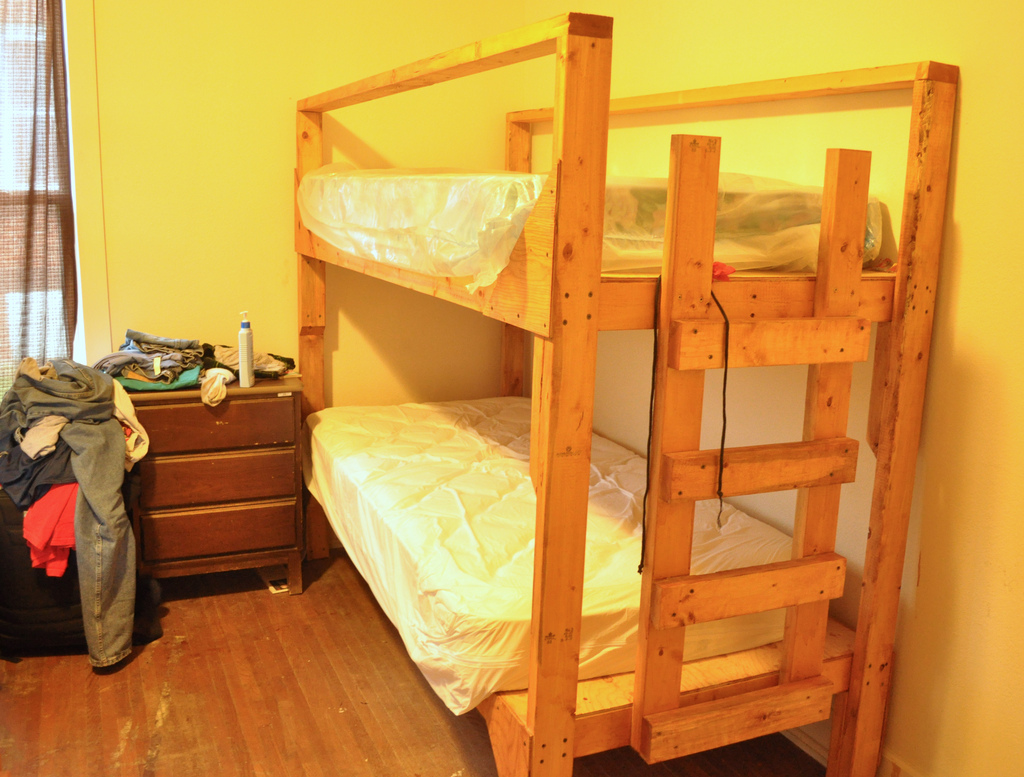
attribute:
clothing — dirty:
[14, 376, 170, 679]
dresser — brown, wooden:
[111, 363, 306, 625]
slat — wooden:
[664, 547, 861, 640]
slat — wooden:
[291, 113, 337, 395]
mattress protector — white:
[415, 627, 552, 705]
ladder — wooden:
[667, 253, 916, 705]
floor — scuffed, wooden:
[91, 636, 174, 771]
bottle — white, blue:
[222, 303, 270, 397]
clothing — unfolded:
[30, 357, 143, 602]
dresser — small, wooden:
[121, 379, 336, 619]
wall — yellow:
[80, 7, 716, 682]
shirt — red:
[19, 471, 108, 605]